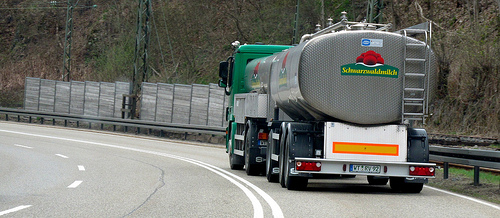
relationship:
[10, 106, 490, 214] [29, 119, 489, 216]
curve in road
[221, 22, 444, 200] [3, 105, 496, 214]
truck on road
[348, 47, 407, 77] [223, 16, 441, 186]
tag on truck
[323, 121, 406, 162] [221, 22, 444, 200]
tag on truck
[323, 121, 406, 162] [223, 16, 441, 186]
tag on truck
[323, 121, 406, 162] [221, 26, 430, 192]
tag on truck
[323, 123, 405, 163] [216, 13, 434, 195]
tag on truck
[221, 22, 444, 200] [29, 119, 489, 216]
truck driving down road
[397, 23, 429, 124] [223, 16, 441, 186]
ladder on truck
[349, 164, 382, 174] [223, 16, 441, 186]
license plate on truck